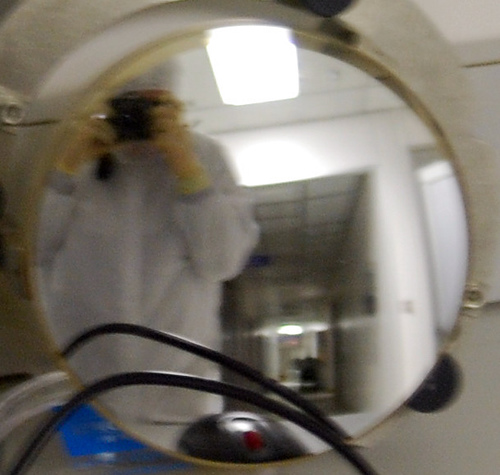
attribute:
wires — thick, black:
[0, 318, 383, 474]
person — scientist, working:
[33, 55, 262, 425]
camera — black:
[95, 92, 166, 147]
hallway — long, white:
[216, 169, 390, 434]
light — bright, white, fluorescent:
[279, 316, 310, 341]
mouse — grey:
[171, 400, 313, 462]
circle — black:
[400, 349, 470, 415]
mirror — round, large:
[26, 25, 475, 467]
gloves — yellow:
[59, 99, 197, 206]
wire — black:
[0, 369, 373, 474]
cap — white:
[114, 56, 190, 100]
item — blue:
[54, 400, 156, 463]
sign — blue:
[242, 247, 276, 272]